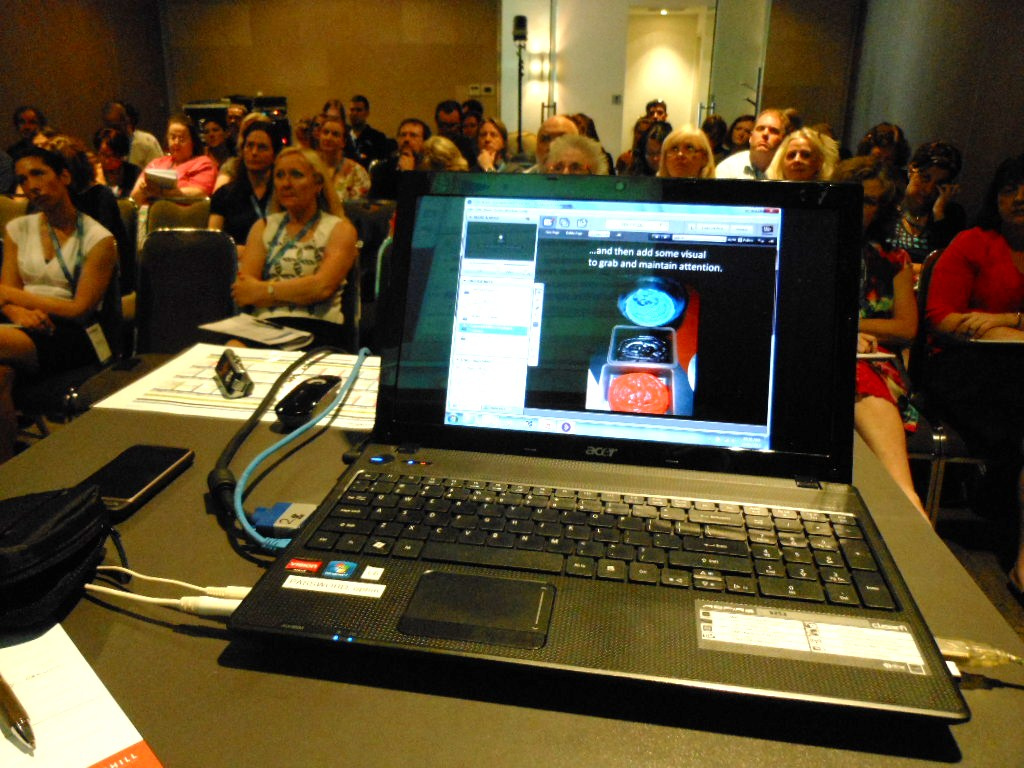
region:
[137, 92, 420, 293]
this is a crowd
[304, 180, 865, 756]
this is a laptop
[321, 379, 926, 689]
the laptop is black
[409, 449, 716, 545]
the keys are black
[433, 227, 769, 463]
the laptop is on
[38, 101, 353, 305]
the people are paying attention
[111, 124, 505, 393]
the people are watching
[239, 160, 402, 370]
the woman has her arms crossed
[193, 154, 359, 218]
the woman has gray hair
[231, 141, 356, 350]
woman sitting with her arms crossed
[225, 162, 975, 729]
open black laptop on a table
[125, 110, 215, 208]
woman wearing coral colored shirt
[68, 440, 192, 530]
silver and black smartphone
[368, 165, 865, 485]
computer program on computer screen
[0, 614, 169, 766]
brown pen on top of white paper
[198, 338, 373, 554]
blue cord and black cord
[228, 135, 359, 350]
woman wearing lanyard and white sleeveless shirt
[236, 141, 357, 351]
woman with blonde hair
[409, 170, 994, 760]
black computer on table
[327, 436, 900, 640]
black keys on laptop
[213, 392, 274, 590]
black cable on laptop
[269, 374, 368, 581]
blue ethernet cable in laptop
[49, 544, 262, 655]
white cords in laptop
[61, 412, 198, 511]
black phone on table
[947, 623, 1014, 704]
clear cable connected into laptop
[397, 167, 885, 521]
presentation appears on screen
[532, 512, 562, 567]
a button on the keyboard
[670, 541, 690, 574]
a button on the keyboard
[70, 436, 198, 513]
a black and gray cellphone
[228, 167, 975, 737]
a black laptop computer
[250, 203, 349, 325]
a woman's white tank top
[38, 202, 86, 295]
a green and white lanyard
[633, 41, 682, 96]
a light shadow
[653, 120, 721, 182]
a woman's blonde hair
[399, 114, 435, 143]
a man's short cut hair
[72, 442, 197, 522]
Cellphone sitting on table.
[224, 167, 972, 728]
Open laptop displaying presentation.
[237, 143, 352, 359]
Woman sitting in audience.